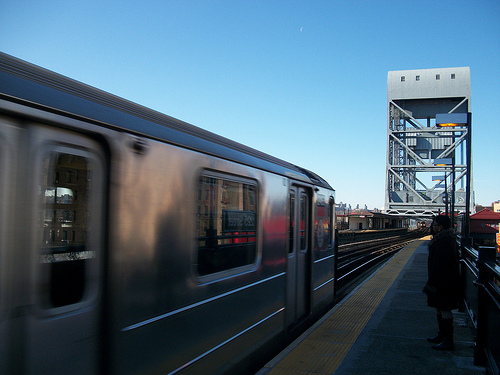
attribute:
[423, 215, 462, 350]
woman — waiting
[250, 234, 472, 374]
platform — yellow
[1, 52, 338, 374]
train — silver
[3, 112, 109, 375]
door — closed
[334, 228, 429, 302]
railroad — parallel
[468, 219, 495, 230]
roof — red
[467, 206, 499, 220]
roof — red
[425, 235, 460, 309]
coat — fur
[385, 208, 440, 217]
overpass — steel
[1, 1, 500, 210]
sky — blue